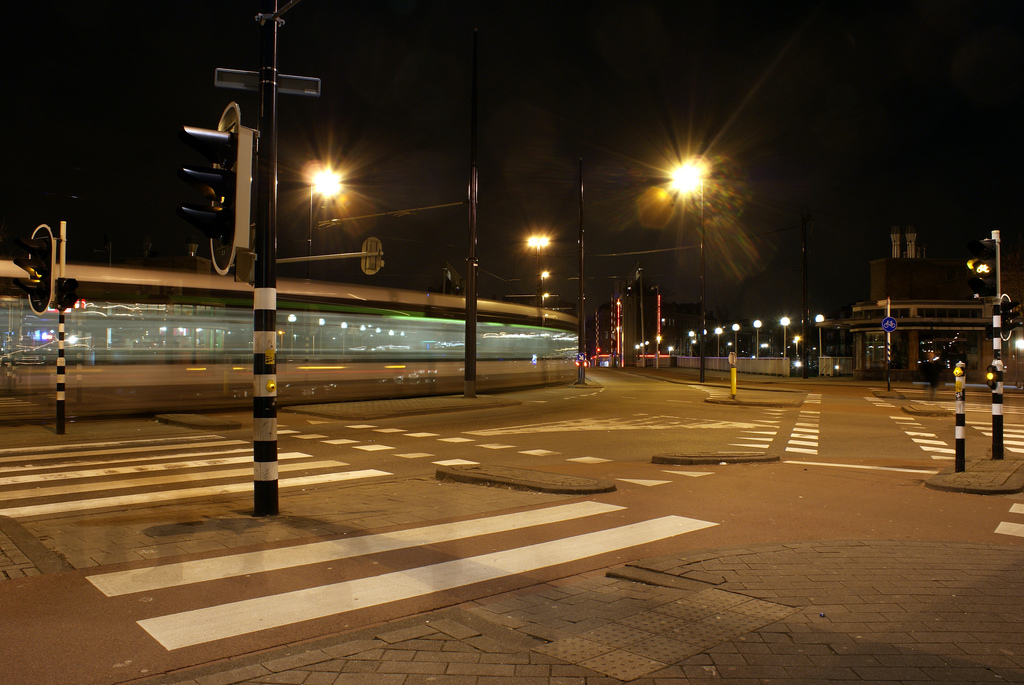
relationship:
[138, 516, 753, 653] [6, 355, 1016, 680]
line on road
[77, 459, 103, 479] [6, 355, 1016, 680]
line on road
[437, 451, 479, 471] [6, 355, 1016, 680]
line on road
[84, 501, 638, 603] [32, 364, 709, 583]
line on road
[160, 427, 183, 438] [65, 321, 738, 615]
line on road